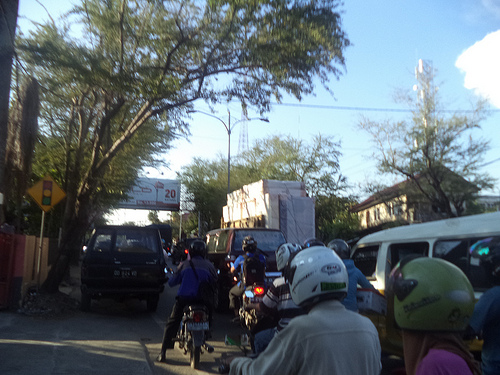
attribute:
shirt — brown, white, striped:
[276, 278, 333, 340]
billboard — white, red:
[117, 178, 181, 209]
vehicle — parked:
[86, 222, 165, 310]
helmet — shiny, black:
[182, 237, 211, 262]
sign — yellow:
[26, 170, 67, 212]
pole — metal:
[32, 211, 47, 283]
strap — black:
[178, 251, 203, 282]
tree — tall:
[350, 51, 498, 230]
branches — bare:
[399, 133, 461, 178]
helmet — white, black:
[291, 245, 353, 302]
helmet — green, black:
[390, 252, 477, 334]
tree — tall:
[2, 2, 349, 302]